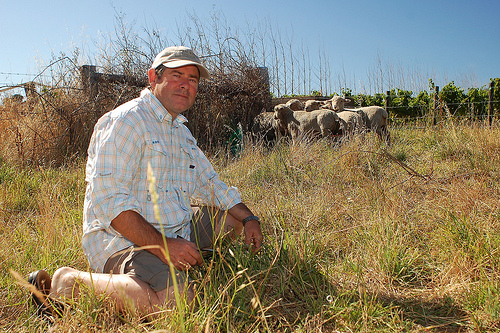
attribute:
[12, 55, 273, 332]
man — sitting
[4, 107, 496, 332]
field — green, grassy, overgrown, unruly, brown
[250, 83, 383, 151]
sheep — fenced in, white, grouped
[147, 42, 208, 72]
hat — tan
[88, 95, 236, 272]
shirt — striped, cotton, plaid, buttoned up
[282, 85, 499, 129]
plants — growing, green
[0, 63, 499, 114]
fence — barbed wire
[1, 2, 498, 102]
sky — blue, clear, cloudless, beautiful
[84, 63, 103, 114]
post — wooden